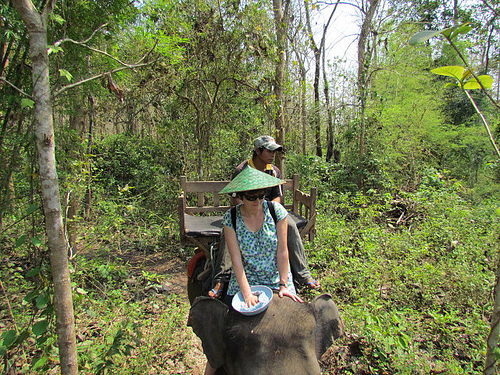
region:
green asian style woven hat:
[219, 165, 282, 193]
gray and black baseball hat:
[251, 135, 279, 150]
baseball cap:
[252, 132, 280, 152]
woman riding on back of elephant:
[223, 164, 300, 312]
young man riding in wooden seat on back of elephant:
[174, 133, 314, 276]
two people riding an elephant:
[178, 134, 343, 374]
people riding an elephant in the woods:
[1, 0, 498, 374]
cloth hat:
[233, 284, 272, 314]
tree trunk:
[20, 0, 81, 373]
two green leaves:
[431, 65, 493, 90]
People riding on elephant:
[206, 138, 322, 315]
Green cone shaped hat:
[220, 160, 287, 195]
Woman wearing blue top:
[221, 203, 298, 295]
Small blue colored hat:
[229, 284, 276, 315]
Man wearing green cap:
[254, 132, 282, 162]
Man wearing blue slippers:
[299, 277, 325, 289]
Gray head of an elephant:
[186, 292, 346, 373]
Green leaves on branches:
[403, 27, 487, 95]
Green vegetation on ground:
[324, 204, 494, 366]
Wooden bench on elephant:
[176, 174, 321, 237]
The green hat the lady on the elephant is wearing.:
[220, 170, 279, 189]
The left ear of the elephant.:
[185, 300, 233, 360]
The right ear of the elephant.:
[315, 290, 340, 351]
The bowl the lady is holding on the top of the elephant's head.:
[232, 284, 275, 314]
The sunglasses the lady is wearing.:
[245, 190, 265, 203]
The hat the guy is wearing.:
[252, 133, 283, 155]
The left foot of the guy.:
[210, 282, 222, 300]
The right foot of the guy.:
[305, 277, 319, 290]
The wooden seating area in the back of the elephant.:
[174, 170, 311, 235]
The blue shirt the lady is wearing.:
[221, 205, 278, 287]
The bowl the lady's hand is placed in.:
[220, 280, 272, 313]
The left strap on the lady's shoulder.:
[223, 205, 238, 225]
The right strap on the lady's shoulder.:
[265, 200, 275, 220]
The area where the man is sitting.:
[187, 191, 304, 249]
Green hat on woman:
[215, 158, 294, 199]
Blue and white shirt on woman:
[210, 200, 313, 299]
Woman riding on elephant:
[147, 166, 367, 373]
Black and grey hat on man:
[248, 131, 289, 153]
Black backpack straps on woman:
[222, 198, 289, 231]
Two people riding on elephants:
[1, 0, 499, 372]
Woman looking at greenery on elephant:
[207, 153, 309, 315]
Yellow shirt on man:
[229, 149, 279, 181]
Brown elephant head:
[182, 285, 343, 374]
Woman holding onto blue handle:
[230, 276, 278, 321]